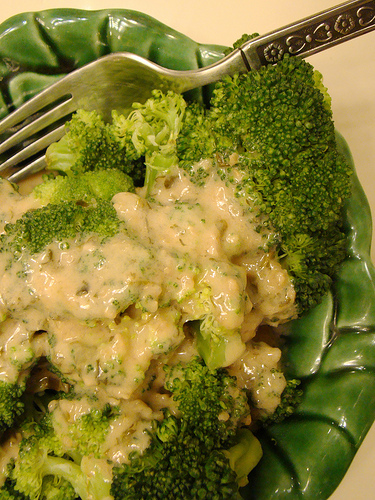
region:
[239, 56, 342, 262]
a head of raw broccoli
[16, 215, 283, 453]
broccoli covered in cheese sauce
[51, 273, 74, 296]
yellow cheese sauce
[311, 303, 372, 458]
a leaf pattern in a bowl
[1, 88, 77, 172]
the silver tines of a fork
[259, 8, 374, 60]
decorative pattern on a fork handle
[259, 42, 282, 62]
a flower design on a fork handle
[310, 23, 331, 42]
a heart design on a fork handle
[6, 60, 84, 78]
black paint in the bowl cracks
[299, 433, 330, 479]
green paint on a ceramic bowl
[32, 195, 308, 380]
Sauce on broccoli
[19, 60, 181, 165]
End of fork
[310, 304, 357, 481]
Edge of green bowl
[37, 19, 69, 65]
Groove in bowl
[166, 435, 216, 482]
Sproutlets of broccoli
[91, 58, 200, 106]
Fork is silver and shiny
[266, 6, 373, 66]
Pattern on fork's handle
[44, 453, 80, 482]
Portion of stalk of vegetable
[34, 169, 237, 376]
Broccoli is mushy with sauce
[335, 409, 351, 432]
Shiny part of bowl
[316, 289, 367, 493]
Edge of green salad plate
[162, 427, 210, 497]
Broccoli florette upclose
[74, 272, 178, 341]
Creamy cheese sauce over broccoli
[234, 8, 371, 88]
Silverware pattern that has been in use since 1970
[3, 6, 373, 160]
Fork with fancy design on handle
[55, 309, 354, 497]
Broccolii and cheese on a green plate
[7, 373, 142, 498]
Vegetable and protein should taste good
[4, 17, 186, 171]
Ceramic serving dish with fork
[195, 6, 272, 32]
tan background to not distract from food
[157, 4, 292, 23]
Tan tablecloth without decoration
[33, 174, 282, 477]
broccoli with cheese sauce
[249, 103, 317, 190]
green steamed broccolli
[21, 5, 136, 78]
a green ceramic bowl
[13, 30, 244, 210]
a fork with 4 tines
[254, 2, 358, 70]
a fork with decoration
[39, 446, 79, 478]
the stalk of a broccoli floret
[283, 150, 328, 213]
small broccoli florets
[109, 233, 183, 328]
a cream based sauce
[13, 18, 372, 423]
a vegetable based side dish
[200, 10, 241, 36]
a white tabletop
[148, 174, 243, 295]
cheese sauce covers the broccoli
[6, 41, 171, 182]
a metal fork resting on the green bowl containing the broccoli and cheese sauce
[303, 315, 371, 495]
a flower on the metal fork's handle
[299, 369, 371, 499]
the edge of the green bowl containing the broccoli and cheese sauce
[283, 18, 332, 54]
a design of two hearts and a dot on the handle of the metal fork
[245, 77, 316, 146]
the floret of the broccoli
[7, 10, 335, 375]
a delicious-looking dish of broccoli casserole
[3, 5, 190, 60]
the edge of the bowl looks like cabbage leaves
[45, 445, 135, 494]
the stem of the broccoli is also eaten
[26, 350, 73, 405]
a piece of mushroom adds flavor to the broccoli and cheese sauce dish